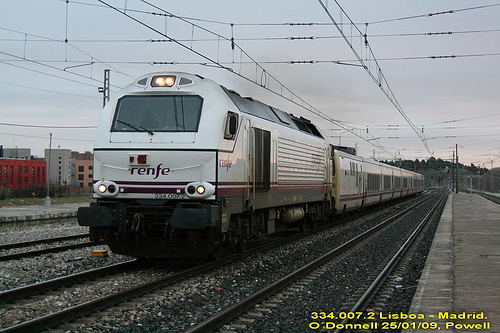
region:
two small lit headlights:
[102, 40, 211, 124]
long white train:
[59, 39, 456, 266]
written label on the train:
[110, 152, 185, 192]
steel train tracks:
[149, 164, 474, 298]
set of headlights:
[82, 165, 222, 207]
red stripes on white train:
[214, 124, 366, 205]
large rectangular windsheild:
[104, 85, 208, 136]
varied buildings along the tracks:
[1, 114, 117, 210]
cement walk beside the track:
[433, 178, 496, 317]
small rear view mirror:
[220, 108, 250, 151]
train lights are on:
[127, 66, 204, 106]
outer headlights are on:
[58, 167, 218, 217]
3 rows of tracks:
[2, 212, 369, 319]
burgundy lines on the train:
[67, 172, 256, 205]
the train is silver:
[49, 75, 344, 221]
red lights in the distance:
[370, 157, 459, 202]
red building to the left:
[1, 141, 55, 193]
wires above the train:
[80, 4, 485, 121]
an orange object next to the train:
[75, 245, 112, 263]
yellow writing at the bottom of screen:
[295, 299, 497, 329]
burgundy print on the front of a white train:
[125, 165, 175, 180]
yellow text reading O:
[305, 320, 324, 332]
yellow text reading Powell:
[443, 318, 498, 329]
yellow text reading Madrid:
[438, 309, 493, 320]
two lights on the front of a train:
[182, 181, 214, 196]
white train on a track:
[74, 71, 438, 256]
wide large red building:
[2, 153, 49, 193]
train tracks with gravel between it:
[2, 248, 437, 330]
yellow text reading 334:
[311, 308, 336, 319]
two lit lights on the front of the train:
[146, 75, 182, 88]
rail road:
[262, 258, 402, 326]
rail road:
[244, 248, 336, 322]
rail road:
[272, 222, 432, 316]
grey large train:
[90, 78, 428, 229]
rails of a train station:
[0, 161, 445, 326]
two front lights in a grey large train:
[83, 177, 211, 202]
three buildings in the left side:
[0, 142, 101, 203]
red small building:
[3, 154, 47, 196]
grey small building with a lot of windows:
[46, 140, 73, 192]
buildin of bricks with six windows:
[75, 157, 97, 191]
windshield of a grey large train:
[115, 91, 207, 132]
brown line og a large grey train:
[216, 172, 337, 202]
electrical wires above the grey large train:
[0, 5, 491, 100]